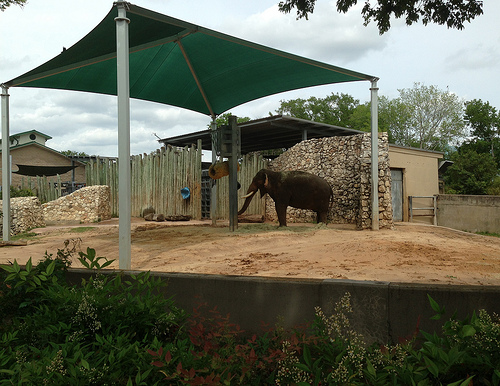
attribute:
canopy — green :
[1, 0, 378, 273]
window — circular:
[28, 130, 37, 142]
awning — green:
[4, 2, 379, 158]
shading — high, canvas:
[25, 10, 389, 265]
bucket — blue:
[169, 177, 199, 207]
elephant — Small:
[237, 169, 337, 226]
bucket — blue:
[166, 178, 205, 203]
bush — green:
[4, 238, 189, 382]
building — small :
[167, 102, 464, 242]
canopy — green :
[133, 0, 400, 194]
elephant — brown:
[227, 170, 338, 227]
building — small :
[388, 149, 450, 225]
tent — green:
[6, 12, 380, 249]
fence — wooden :
[81, 137, 203, 223]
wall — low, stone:
[0, 191, 48, 236]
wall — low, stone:
[38, 180, 112, 221]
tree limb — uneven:
[106, 158, 116, 221]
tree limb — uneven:
[135, 152, 139, 216]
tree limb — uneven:
[191, 135, 202, 219]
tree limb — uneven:
[187, 141, 193, 220]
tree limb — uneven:
[173, 144, 180, 218]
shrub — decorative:
[313, 290, 357, 363]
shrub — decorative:
[153, 302, 311, 381]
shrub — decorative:
[1, 244, 183, 384]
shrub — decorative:
[400, 285, 484, 384]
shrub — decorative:
[310, 290, 384, 382]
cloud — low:
[234, 1, 391, 69]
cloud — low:
[438, 41, 484, 76]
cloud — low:
[1, 51, 32, 79]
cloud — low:
[74, 127, 146, 144]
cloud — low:
[29, 101, 69, 118]